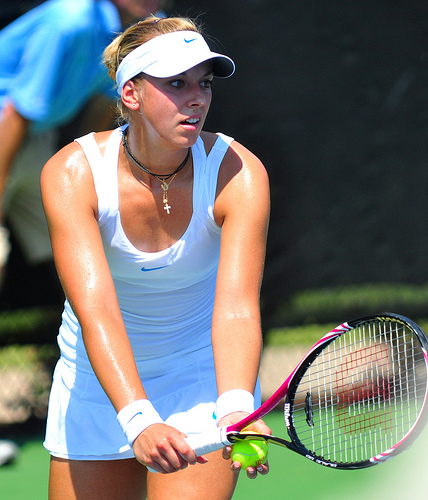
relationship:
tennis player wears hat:
[38, 13, 273, 500] [114, 29, 235, 94]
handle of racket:
[169, 407, 248, 469] [138, 305, 427, 477]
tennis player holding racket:
[38, 13, 273, 500] [138, 305, 427, 477]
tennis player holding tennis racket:
[38, 13, 273, 500] [147, 309, 427, 474]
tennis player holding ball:
[38, 13, 273, 500] [228, 431, 267, 470]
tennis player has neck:
[38, 13, 273, 500] [121, 125, 191, 194]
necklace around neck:
[124, 125, 189, 215] [121, 125, 191, 194]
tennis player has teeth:
[38, 13, 273, 500] [186, 116, 200, 124]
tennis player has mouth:
[38, 13, 273, 500] [179, 113, 204, 131]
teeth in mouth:
[186, 116, 200, 124] [179, 113, 204, 131]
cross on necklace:
[162, 203, 171, 215] [120, 125, 190, 215]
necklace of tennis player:
[120, 125, 190, 215] [38, 13, 273, 500]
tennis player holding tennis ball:
[38, 13, 273, 500] [230, 437, 270, 468]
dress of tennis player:
[41, 124, 265, 461] [38, 13, 273, 500]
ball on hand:
[216, 423, 285, 489] [120, 392, 220, 481]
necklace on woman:
[124, 125, 189, 215] [33, 9, 271, 350]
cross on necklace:
[154, 199, 178, 215] [96, 153, 217, 255]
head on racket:
[274, 301, 426, 475] [138, 305, 427, 477]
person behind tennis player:
[0, 0, 168, 469] [38, 13, 273, 498]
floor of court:
[276, 407, 419, 498] [13, 350, 412, 497]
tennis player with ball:
[38, 13, 273, 500] [227, 426, 267, 471]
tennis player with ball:
[38, 13, 273, 500] [218, 422, 274, 466]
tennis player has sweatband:
[38, 13, 273, 500] [215, 387, 254, 420]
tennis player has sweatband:
[38, 13, 273, 500] [117, 397, 164, 443]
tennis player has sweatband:
[38, 13, 273, 500] [215, 385, 257, 414]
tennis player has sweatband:
[38, 13, 273, 500] [116, 397, 158, 442]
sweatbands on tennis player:
[116, 388, 255, 446] [38, 13, 273, 500]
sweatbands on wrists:
[116, 388, 255, 446] [114, 390, 255, 437]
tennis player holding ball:
[38, 13, 273, 500] [226, 429, 273, 464]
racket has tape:
[223, 333, 424, 470] [164, 416, 237, 462]